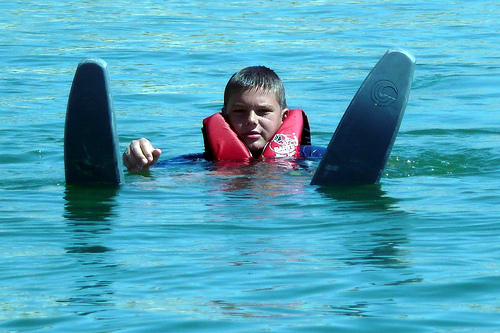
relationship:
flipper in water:
[300, 42, 420, 198] [2, 2, 497, 331]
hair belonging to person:
[218, 64, 288, 115] [120, 60, 335, 173]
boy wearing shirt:
[119, 63, 328, 177] [150, 134, 332, 171]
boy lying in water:
[121, 65, 326, 172] [2, 2, 497, 331]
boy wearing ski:
[119, 63, 328, 177] [328, 47, 413, 182]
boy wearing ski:
[119, 63, 328, 177] [64, 58, 119, 178]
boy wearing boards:
[119, 63, 328, 177] [60, 54, 127, 189]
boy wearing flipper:
[119, 63, 328, 177] [300, 42, 420, 198]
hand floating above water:
[123, 137, 160, 172] [2, 2, 497, 331]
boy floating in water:
[119, 63, 328, 177] [2, 2, 497, 331]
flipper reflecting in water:
[300, 42, 420, 198] [2, 2, 497, 331]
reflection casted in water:
[321, 181, 422, 289] [2, 2, 497, 331]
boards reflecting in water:
[60, 54, 127, 189] [2, 2, 497, 331]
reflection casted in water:
[56, 190, 123, 316] [2, 2, 497, 331]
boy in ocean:
[119, 63, 328, 177] [1, 0, 498, 327]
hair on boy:
[218, 64, 288, 115] [121, 65, 326, 172]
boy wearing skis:
[121, 65, 326, 172] [61, 47, 419, 190]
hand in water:
[120, 137, 162, 175] [9, 182, 497, 329]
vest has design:
[202, 102, 312, 167] [268, 128, 298, 163]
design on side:
[268, 128, 298, 163] [254, 101, 307, 181]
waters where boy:
[7, 179, 497, 329] [119, 63, 328, 177]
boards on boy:
[60, 54, 127, 189] [106, 50, 336, 195]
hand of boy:
[120, 137, 162, 175] [47, 16, 421, 238]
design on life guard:
[268, 128, 301, 162] [195, 108, 307, 170]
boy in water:
[119, 63, 328, 177] [4, 146, 498, 328]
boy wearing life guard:
[121, 65, 326, 172] [199, 107, 313, 181]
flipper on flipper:
[300, 42, 420, 198] [300, 42, 420, 198]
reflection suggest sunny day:
[321, 193, 428, 291] [31, 16, 101, 60]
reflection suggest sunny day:
[56, 190, 123, 316] [31, 16, 101, 60]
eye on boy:
[253, 107, 270, 114] [119, 63, 328, 177]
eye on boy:
[229, 109, 245, 114] [119, 63, 328, 177]